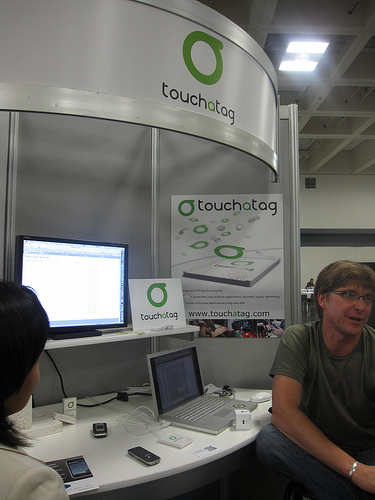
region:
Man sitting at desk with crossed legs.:
[251, 257, 373, 498]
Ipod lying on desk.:
[157, 430, 192, 449]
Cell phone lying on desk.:
[90, 416, 111, 440]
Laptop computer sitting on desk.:
[145, 339, 261, 435]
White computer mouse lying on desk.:
[248, 388, 273, 404]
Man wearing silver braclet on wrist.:
[344, 454, 363, 482]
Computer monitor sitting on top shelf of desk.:
[9, 226, 133, 341]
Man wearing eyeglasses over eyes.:
[328, 281, 374, 306]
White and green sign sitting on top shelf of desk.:
[127, 274, 192, 334]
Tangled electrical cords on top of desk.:
[100, 381, 154, 436]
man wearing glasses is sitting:
[256, 260, 373, 499]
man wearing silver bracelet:
[346, 458, 358, 478]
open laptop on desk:
[147, 345, 258, 435]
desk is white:
[0, 383, 301, 498]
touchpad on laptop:
[213, 405, 234, 417]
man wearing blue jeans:
[253, 421, 370, 499]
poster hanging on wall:
[170, 193, 291, 338]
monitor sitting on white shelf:
[13, 234, 131, 341]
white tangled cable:
[87, 393, 168, 438]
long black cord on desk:
[43, 347, 152, 408]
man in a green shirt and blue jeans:
[258, 261, 374, 494]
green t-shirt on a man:
[272, 320, 373, 450]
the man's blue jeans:
[256, 426, 359, 498]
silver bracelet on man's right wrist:
[349, 460, 358, 478]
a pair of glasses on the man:
[325, 290, 371, 302]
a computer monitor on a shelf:
[17, 232, 128, 332]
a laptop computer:
[146, 347, 255, 433]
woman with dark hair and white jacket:
[1, 284, 70, 498]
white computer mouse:
[250, 390, 270, 402]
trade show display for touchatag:
[1, 2, 302, 494]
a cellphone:
[126, 445, 162, 468]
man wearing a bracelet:
[340, 460, 364, 475]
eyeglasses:
[339, 291, 372, 301]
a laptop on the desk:
[145, 358, 239, 429]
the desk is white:
[87, 443, 120, 469]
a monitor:
[28, 243, 128, 325]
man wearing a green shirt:
[307, 360, 371, 418]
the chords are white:
[119, 408, 165, 439]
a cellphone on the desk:
[87, 419, 107, 440]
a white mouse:
[253, 390, 269, 401]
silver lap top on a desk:
[143, 343, 260, 435]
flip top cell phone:
[91, 419, 109, 442]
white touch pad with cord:
[117, 406, 194, 447]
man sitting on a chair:
[254, 257, 374, 497]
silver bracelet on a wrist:
[342, 456, 362, 481]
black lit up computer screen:
[15, 232, 129, 330]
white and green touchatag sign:
[126, 276, 187, 330]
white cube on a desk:
[233, 406, 252, 430]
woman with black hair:
[0, 279, 71, 498]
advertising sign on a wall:
[170, 192, 288, 340]